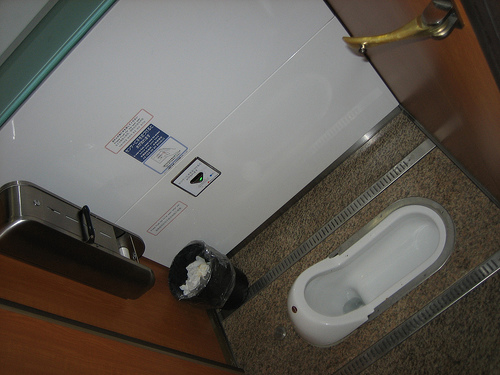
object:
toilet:
[276, 201, 457, 350]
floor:
[223, 299, 291, 373]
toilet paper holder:
[2, 181, 159, 301]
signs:
[148, 202, 184, 237]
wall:
[0, 3, 376, 199]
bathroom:
[2, 3, 499, 375]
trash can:
[157, 239, 252, 314]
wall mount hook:
[333, 3, 459, 51]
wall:
[0, 218, 234, 374]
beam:
[4, 5, 112, 127]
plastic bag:
[169, 247, 236, 309]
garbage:
[174, 254, 211, 295]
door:
[327, 0, 500, 208]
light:
[198, 174, 205, 185]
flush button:
[271, 320, 286, 344]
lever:
[76, 202, 99, 242]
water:
[329, 285, 365, 317]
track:
[327, 266, 499, 375]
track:
[316, 137, 434, 241]